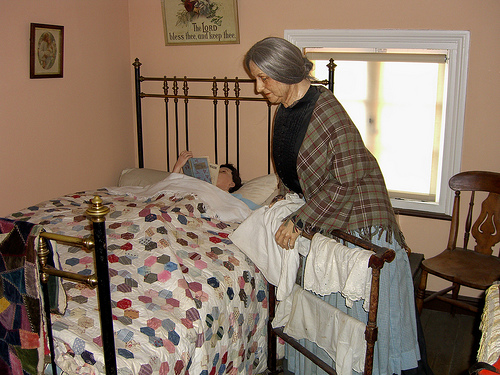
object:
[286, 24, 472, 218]
window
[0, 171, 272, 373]
quilt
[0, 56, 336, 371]
bed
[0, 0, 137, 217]
wall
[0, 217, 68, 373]
quilt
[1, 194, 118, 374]
footboard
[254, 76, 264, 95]
nose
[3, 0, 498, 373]
room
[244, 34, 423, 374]
old woman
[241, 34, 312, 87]
gray hair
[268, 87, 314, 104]
neck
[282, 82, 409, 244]
shall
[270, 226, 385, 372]
quilt rack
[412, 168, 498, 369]
chair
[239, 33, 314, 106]
head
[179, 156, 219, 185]
book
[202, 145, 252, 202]
head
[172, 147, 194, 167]
hand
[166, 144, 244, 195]
boy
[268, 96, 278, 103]
chin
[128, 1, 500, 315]
wall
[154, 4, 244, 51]
picture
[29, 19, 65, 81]
picture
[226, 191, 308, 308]
linen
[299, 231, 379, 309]
linen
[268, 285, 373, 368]
linen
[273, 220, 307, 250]
hand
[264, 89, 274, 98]
mouth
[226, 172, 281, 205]
pillow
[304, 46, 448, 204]
blind